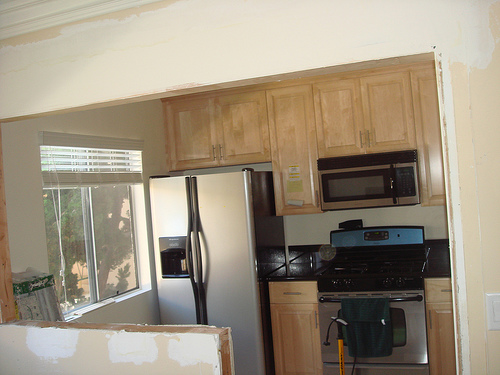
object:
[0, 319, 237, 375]
kitchen wall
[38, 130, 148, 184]
blinds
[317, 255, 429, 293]
stove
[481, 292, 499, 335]
plate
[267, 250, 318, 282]
countertop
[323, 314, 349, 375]
pump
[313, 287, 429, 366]
oven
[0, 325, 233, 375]
wall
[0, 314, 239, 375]
wooden partition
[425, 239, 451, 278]
countertops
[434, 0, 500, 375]
wall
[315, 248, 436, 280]
range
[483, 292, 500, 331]
light switch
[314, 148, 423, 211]
microwave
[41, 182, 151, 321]
window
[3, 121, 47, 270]
wall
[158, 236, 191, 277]
ice water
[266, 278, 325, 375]
cabinets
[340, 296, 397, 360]
towel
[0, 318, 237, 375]
drywall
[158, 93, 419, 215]
cabinets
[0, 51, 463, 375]
kitchen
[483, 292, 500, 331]
switch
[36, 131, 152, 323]
window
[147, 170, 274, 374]
fridge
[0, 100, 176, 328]
wall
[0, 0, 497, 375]
wall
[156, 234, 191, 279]
ice maker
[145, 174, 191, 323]
door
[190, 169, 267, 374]
door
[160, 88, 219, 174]
cabinet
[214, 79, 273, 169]
cabinet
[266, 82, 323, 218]
cabinet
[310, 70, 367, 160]
cabinet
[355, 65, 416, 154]
cabinet